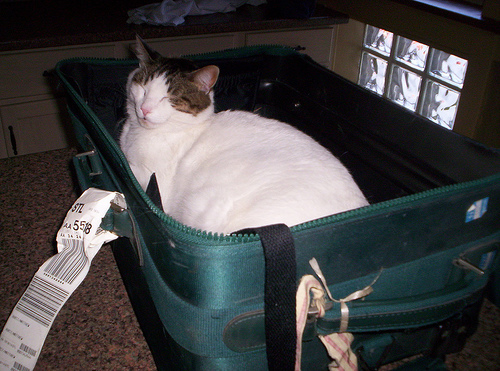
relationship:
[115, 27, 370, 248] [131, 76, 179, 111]
cat with eyes